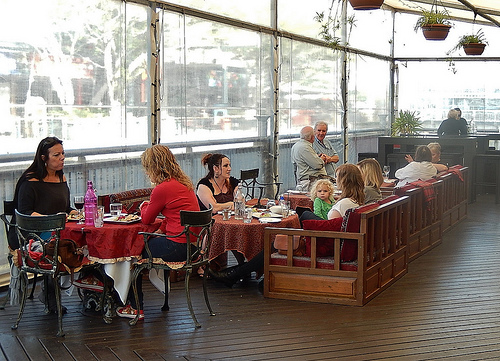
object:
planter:
[348, 0, 384, 10]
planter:
[421, 25, 452, 41]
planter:
[463, 43, 486, 55]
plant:
[313, 0, 357, 63]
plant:
[409, 0, 456, 34]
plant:
[445, 26, 492, 75]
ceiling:
[382, 0, 500, 27]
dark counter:
[376, 129, 500, 204]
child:
[310, 178, 337, 220]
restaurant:
[0, 0, 500, 361]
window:
[0, 0, 151, 169]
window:
[159, 9, 268, 151]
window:
[279, 38, 342, 145]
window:
[346, 51, 394, 135]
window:
[394, 60, 498, 149]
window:
[345, 0, 394, 54]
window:
[272, 0, 345, 44]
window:
[159, 0, 272, 26]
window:
[388, 0, 500, 62]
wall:
[0, 0, 500, 204]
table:
[60, 212, 164, 325]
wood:
[0, 193, 500, 361]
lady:
[68, 143, 204, 320]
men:
[291, 120, 341, 191]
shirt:
[139, 177, 205, 243]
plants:
[231, 34, 328, 125]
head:
[335, 163, 366, 194]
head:
[356, 158, 384, 187]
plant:
[389, 109, 426, 138]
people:
[7, 120, 448, 322]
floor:
[0, 190, 499, 361]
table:
[377, 127, 500, 204]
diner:
[217, 177, 297, 227]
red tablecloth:
[59, 216, 161, 264]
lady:
[7, 137, 79, 314]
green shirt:
[313, 195, 337, 219]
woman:
[203, 163, 368, 289]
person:
[437, 109, 467, 141]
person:
[453, 108, 469, 136]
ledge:
[390, 126, 500, 139]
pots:
[337, 0, 484, 59]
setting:
[17, 141, 458, 322]